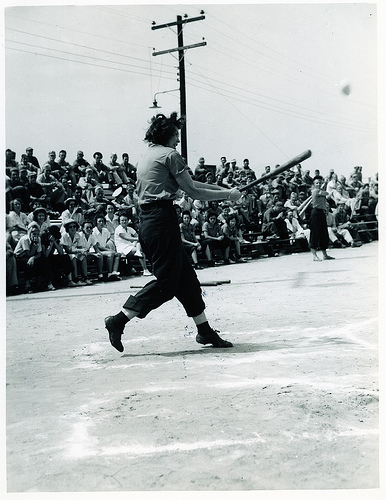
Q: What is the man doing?
A: Swinging a bat.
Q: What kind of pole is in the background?
A: Telephone pole.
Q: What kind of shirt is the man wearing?
A: Short sleeve.